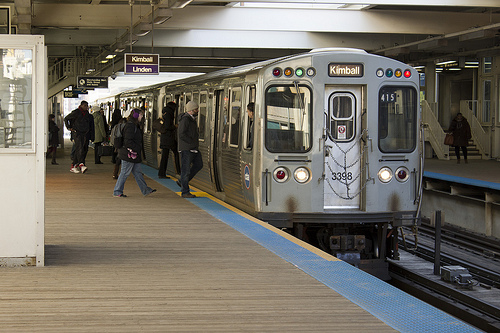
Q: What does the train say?
A: Kimball.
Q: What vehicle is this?
A: Train.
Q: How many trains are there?
A: One.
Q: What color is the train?
A: Silver.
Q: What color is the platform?
A: Tan.